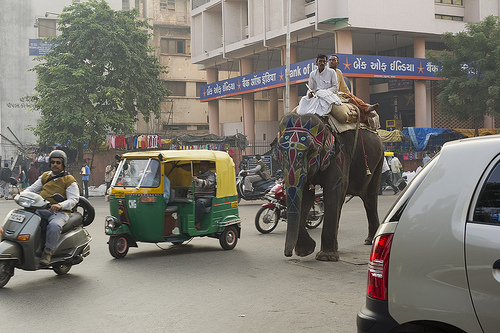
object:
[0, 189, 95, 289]
motorcycle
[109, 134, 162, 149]
clothes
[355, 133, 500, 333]
car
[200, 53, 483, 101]
sign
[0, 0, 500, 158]
building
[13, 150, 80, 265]
man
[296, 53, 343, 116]
man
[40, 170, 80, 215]
vest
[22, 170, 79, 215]
shirt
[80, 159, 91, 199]
man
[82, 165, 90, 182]
blue shirt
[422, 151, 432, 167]
man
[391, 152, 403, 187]
man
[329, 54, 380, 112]
man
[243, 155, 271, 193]
man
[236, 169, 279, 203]
scooter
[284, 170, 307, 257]
trunk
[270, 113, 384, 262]
elephant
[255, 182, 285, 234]
head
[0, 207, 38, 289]
head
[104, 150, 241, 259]
car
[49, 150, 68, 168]
helmet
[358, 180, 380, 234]
leg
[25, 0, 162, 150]
tree leaves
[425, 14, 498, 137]
tree leaves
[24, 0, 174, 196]
tree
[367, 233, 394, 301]
tail lights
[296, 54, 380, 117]
people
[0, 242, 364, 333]
road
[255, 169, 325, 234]
bike